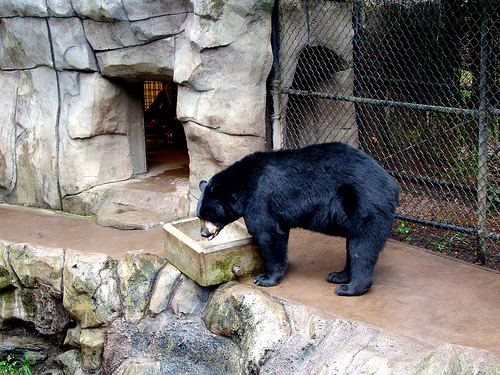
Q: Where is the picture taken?
A: At the zoo.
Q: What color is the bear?
A: Black.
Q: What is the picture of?
A: Bear.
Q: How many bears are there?
A: One.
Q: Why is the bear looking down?
A: To eat.